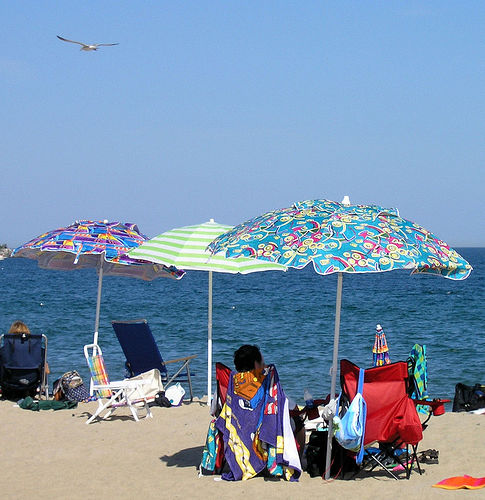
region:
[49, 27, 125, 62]
A bird is flying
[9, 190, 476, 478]
Three umbrellas on the beach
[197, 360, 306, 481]
A colorful beach towel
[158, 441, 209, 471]
Shadow on the sand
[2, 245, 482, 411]
The water is very blue and calm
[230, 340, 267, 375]
Person has dark hair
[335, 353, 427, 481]
A red beach chair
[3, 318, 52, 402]
Person sitting on a beach chair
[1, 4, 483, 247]
The sky is blue and clear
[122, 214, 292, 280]
Green and white striped umbrella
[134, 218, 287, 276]
The green and white umbrella.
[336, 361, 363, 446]
The bag hanging over the red chair.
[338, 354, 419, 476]
The red chair next to the person.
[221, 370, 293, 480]
The towels hanging over the chair.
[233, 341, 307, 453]
The person sitting in the chair where the towels are.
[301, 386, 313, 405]
The bottle of water in the cup holder of the chair.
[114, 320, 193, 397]
The blue empty chair.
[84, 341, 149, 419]
The white chair with a colorful backing.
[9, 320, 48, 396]
The blonde haired person sitting in the blue chair.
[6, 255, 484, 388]
The water in the distance.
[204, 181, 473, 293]
a decorated umbrella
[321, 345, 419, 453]
the seat is red in colour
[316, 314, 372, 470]
a bag is hanged on the seat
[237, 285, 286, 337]
the water is calm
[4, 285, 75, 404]
a lady is basking on the sun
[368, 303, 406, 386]
the umbrella is not open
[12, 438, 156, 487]
the sand is brown in colour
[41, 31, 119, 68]
a bird is on the air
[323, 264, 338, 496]
the pole is white in colour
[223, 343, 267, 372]
the hair is black in colour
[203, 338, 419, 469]
A person sitting under umbrella.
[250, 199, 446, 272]
The umbrella is very colorful.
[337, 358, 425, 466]
A red beach chair on the sand.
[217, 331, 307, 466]
A person sitting in a beach chair.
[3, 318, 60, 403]
A person sitting in the blue beach chair.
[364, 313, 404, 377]
A umbrella not open.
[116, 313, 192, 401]
A blue beach chair with no one sitting in.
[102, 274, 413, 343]
The water is a little choppy.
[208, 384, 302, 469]
A towel over the beach chair.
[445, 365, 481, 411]
A black bag on the sand.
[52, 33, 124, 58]
Seagull flying in the air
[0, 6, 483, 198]
Blue clear sunny skies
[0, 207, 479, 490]
People enjoying the beach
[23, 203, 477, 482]
Three umbrellas sitting beachside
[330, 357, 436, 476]
Blue purse draped over red chair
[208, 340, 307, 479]
Person sitting in chair beachside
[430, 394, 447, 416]
Cup holder on chair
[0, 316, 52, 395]
Blonde person in blue chair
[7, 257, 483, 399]
Blue placid water